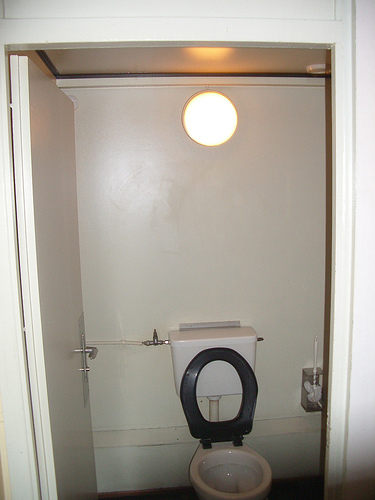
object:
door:
[9, 53, 99, 499]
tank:
[167, 326, 260, 400]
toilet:
[166, 326, 273, 498]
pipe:
[88, 337, 170, 349]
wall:
[57, 84, 326, 435]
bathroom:
[3, 43, 337, 500]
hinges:
[229, 436, 242, 445]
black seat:
[180, 345, 260, 449]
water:
[200, 457, 264, 491]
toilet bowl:
[187, 442, 272, 499]